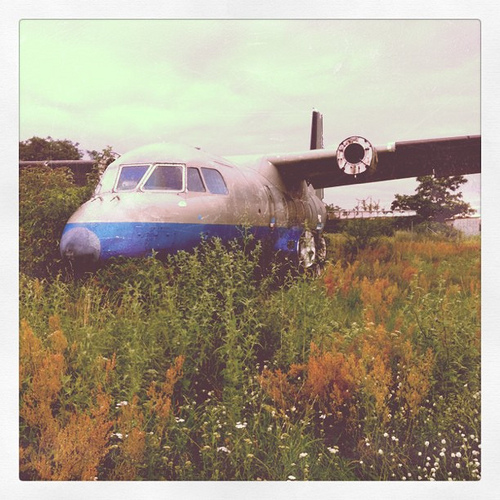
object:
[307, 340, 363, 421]
brown plant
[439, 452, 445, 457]
flowers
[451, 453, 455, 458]
flowers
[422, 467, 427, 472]
flowers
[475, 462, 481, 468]
flowers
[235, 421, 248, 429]
flowers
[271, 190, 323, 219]
windows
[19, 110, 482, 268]
plane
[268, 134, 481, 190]
wing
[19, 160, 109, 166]
wing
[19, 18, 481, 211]
sky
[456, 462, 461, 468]
white flowers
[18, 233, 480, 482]
grass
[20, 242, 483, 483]
vegetation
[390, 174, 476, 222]
tree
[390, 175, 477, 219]
leaves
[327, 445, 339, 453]
white bud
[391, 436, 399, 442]
white bud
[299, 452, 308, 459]
white bud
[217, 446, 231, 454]
white bud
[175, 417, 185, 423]
white bud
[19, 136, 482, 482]
plant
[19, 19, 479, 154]
clouds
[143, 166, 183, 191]
window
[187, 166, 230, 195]
window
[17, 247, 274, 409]
grass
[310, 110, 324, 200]
tail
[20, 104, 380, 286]
man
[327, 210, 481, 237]
building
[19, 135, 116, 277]
greentrees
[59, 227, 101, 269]
nose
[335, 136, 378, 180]
engine